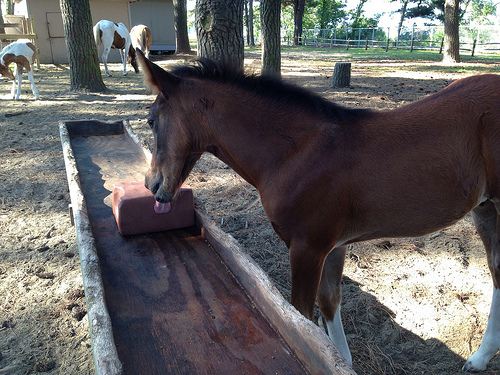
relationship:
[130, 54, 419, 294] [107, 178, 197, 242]
horse licking a block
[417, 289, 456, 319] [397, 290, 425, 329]
dirt on ground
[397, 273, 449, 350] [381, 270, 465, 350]
sunlight on dirt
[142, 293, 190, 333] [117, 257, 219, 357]
water in trough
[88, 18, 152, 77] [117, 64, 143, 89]
horse eating eating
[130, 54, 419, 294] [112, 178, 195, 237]
horse licking block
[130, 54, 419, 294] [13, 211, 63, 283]
horse in field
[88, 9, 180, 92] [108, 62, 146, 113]
horse eating grass